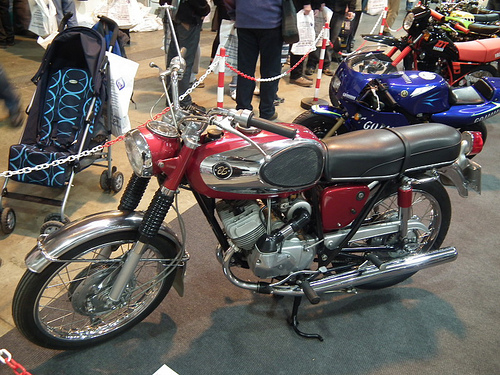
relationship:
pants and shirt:
[233, 24, 283, 121] [230, 0, 282, 28]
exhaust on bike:
[219, 242, 459, 295] [7, 5, 493, 355]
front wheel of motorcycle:
[12, 230, 180, 352] [18, 112, 473, 370]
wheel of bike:
[330, 171, 452, 290] [12, 47, 485, 353]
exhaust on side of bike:
[219, 240, 458, 296] [12, 47, 485, 353]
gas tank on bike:
[174, 113, 324, 201] [12, 47, 485, 353]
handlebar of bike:
[198, 104, 295, 144] [12, 47, 485, 353]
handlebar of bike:
[150, 44, 187, 107] [12, 47, 485, 353]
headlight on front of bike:
[120, 127, 156, 177] [12, 47, 485, 353]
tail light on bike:
[467, 123, 487, 160] [12, 47, 485, 353]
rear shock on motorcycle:
[397, 183, 415, 255] [18, 112, 473, 370]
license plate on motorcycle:
[466, 160, 482, 195] [11, 41, 498, 352]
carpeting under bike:
[3, 203, 495, 373] [12, 47, 485, 353]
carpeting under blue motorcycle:
[3, 203, 495, 373] [291, 50, 500, 159]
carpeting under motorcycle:
[3, 203, 495, 373] [353, 3, 497, 94]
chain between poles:
[4, 8, 385, 178] [128, 6, 361, 121]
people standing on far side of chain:
[152, 6, 380, 107] [213, 26, 324, 88]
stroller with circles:
[5, 18, 191, 238] [2, 67, 97, 187]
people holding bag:
[222, 0, 299, 121] [206, 19, 238, 75]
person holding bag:
[288, 0, 314, 87] [290, 8, 317, 55]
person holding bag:
[304, 0, 337, 75] [314, 5, 333, 46]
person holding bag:
[382, 0, 398, 37] [366, 1, 390, 14]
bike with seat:
[12, 47, 485, 353] [265, 100, 466, 170]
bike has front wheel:
[12, 47, 485, 353] [12, 230, 179, 350]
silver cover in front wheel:
[20, 207, 188, 298] [12, 230, 180, 352]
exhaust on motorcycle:
[219, 242, 459, 295] [11, 41, 498, 352]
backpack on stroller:
[91, 15, 140, 129] [0, 10, 143, 272]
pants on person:
[236, 25, 283, 118] [231, 0, 298, 123]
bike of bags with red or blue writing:
[12, 47, 485, 353] [34, 71, 96, 161]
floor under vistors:
[5, 39, 497, 374] [7, 250, 477, 337]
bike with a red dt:
[12, 47, 485, 353] [190, 183, 270, 316]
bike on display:
[12, 47, 485, 353] [82, 231, 412, 375]